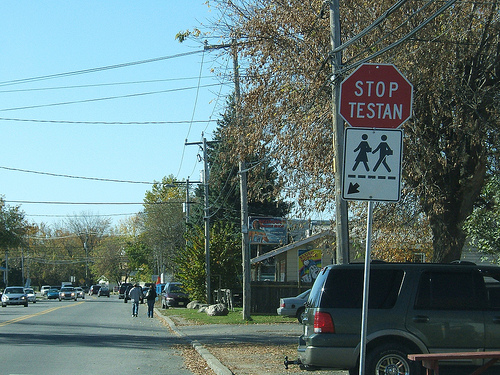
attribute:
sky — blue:
[5, 8, 167, 51]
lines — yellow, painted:
[21, 291, 89, 339]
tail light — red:
[311, 307, 338, 341]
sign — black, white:
[343, 91, 426, 200]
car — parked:
[284, 258, 499, 373]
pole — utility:
[198, 133, 216, 305]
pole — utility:
[181, 174, 193, 304]